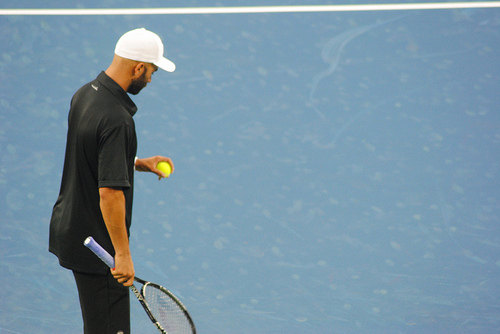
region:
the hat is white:
[110, 24, 186, 72]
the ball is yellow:
[142, 154, 178, 180]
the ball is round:
[149, 152, 177, 187]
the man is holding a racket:
[43, 14, 194, 316]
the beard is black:
[123, 82, 144, 94]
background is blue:
[315, 35, 434, 180]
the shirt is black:
[74, 68, 134, 181]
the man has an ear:
[128, 59, 148, 80]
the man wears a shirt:
[65, 66, 125, 219]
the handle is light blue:
[83, 234, 118, 263]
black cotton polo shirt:
[48, 70, 133, 269]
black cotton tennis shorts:
[69, 267, 132, 332]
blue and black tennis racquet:
[85, 239, 200, 331]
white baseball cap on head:
[113, 25, 178, 75]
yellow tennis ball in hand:
[157, 163, 174, 177]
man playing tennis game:
[51, 25, 196, 330]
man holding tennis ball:
[48, 27, 198, 332]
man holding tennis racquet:
[54, 25, 199, 332]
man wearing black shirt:
[51, 28, 201, 333]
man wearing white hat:
[51, 28, 197, 333]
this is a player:
[36, 14, 260, 331]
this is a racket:
[86, 233, 193, 330]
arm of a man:
[96, 113, 138, 303]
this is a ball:
[149, 148, 180, 195]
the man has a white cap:
[106, 25, 188, 97]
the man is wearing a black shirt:
[35, 60, 140, 270]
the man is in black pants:
[26, 265, 158, 328]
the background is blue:
[209, 119, 321, 234]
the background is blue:
[291, 146, 391, 263]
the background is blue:
[180, 35, 312, 149]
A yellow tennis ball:
[153, 159, 170, 180]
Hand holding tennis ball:
[135, 153, 174, 180]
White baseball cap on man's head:
[111, 25, 176, 73]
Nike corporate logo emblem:
[86, 80, 101, 94]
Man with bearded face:
[124, 62, 152, 94]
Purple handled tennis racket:
[80, 235, 197, 332]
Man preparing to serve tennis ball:
[46, 23, 200, 332]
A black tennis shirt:
[48, 71, 138, 276]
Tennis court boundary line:
[6, 1, 497, 16]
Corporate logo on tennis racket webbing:
[152, 290, 187, 332]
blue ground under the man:
[239, 97, 374, 234]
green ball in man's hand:
[151, 151, 183, 201]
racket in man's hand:
[137, 265, 202, 332]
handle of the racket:
[81, 234, 111, 279]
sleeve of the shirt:
[93, 119, 138, 219]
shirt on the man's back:
[51, 93, 138, 190]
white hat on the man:
[128, 32, 181, 86]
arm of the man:
[107, 195, 132, 266]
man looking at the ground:
[61, 23, 203, 233]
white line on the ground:
[38, 2, 61, 29]